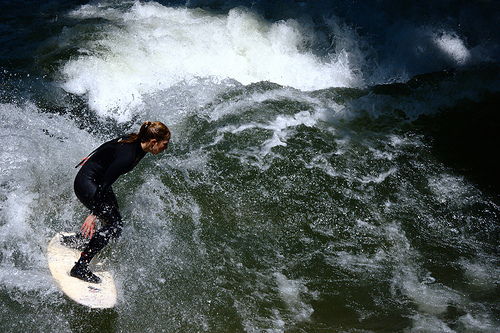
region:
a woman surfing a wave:
[15, 22, 225, 309]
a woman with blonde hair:
[122, 116, 172, 164]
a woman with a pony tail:
[113, 109, 174, 167]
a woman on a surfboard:
[39, 100, 174, 317]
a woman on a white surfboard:
[37, 100, 194, 322]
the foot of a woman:
[70, 259, 105, 289]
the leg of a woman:
[71, 205, 134, 284]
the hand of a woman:
[73, 208, 96, 240]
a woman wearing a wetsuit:
[55, 108, 182, 302]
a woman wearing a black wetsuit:
[34, 107, 179, 317]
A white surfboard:
[46, 228, 120, 308]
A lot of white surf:
[84, 26, 494, 88]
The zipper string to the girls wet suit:
[72, 135, 123, 172]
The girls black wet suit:
[80, 130, 140, 280]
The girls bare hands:
[77, 210, 97, 240]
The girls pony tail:
[130, 120, 155, 136]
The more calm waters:
[248, 117, 469, 328]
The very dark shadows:
[338, 15, 496, 141]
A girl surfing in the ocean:
[40, 120, 173, 311]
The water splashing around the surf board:
[91, 208, 154, 306]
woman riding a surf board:
[60, 91, 198, 331]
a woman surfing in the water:
[51, 91, 189, 331]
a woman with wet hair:
[128, 118, 170, 163]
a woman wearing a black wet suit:
[45, 124, 155, 311]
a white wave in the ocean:
[72, 27, 334, 85]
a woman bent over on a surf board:
[72, 96, 172, 295]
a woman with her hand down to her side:
[67, 138, 146, 258]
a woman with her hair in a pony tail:
[113, 111, 173, 168]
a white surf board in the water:
[25, 226, 135, 325]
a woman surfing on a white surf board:
[12, 96, 187, 331]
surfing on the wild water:
[20, 12, 471, 319]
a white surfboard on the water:
[39, 211, 145, 317]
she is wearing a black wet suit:
[59, 137, 154, 303]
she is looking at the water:
[109, 111, 176, 156]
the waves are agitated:
[84, 19, 361, 113]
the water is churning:
[194, 109, 499, 308]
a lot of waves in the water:
[14, 105, 491, 312]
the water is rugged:
[15, 19, 484, 276]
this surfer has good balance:
[29, 107, 201, 309]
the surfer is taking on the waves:
[34, 51, 469, 319]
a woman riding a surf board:
[31, 99, 199, 324]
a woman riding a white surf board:
[42, 116, 183, 316]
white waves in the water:
[100, 31, 387, 114]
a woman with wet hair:
[117, 107, 176, 153]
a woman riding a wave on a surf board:
[13, 93, 353, 325]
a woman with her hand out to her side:
[67, 115, 177, 267]